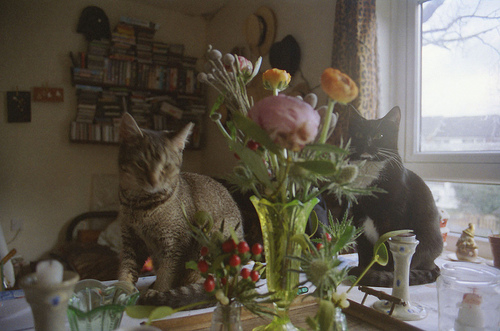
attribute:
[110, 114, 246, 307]
cat — grey, sitting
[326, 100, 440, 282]
cat — black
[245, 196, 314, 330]
vase — yellow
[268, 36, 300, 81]
hat — hanging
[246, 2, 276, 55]
hat — hanging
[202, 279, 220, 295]
berry — red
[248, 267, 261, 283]
berry — red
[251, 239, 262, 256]
berry — red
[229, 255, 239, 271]
berry — red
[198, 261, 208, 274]
berry — red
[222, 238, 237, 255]
berry — red